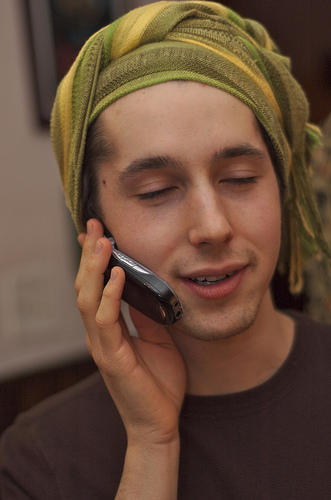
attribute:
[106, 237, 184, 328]
phone — black, flip, open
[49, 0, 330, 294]
cover — green, yellow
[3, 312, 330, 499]
shirt — brown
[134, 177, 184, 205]
eye — closed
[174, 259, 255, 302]
mouth — open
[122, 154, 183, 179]
eyebrow — dark, bushy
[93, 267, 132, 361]
finger — pink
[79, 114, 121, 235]
hair — dark, brown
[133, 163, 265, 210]
eyes — closed